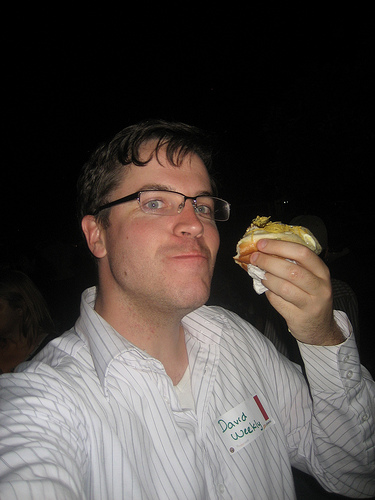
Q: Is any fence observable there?
A: No, there are no fences.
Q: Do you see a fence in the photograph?
A: No, there are no fences.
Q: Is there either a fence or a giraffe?
A: No, there are no fences or giraffes.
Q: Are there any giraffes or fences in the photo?
A: No, there are no fences or giraffes.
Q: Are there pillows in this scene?
A: No, there are no pillows.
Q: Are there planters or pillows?
A: No, there are no pillows or planters.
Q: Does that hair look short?
A: Yes, the hair is short.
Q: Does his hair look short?
A: Yes, the hair is short.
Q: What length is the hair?
A: The hair is short.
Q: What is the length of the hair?
A: The hair is short.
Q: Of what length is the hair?
A: The hair is short.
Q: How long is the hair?
A: The hair is short.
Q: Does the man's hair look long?
A: No, the hair is short.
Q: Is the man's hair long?
A: No, the hair is short.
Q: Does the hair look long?
A: No, the hair is short.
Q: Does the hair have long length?
A: No, the hair is short.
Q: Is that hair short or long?
A: The hair is short.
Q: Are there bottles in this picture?
A: No, there are no bottles.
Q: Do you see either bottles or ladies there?
A: No, there are no bottles or ladies.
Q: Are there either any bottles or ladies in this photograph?
A: No, there are no bottles or ladies.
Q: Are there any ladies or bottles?
A: No, there are no bottles or ladies.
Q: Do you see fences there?
A: No, there are no fences.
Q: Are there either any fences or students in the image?
A: No, there are no fences or students.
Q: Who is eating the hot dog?
A: The man is eating the hot dog.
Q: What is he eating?
A: The man is eating a hot dog.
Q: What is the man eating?
A: The man is eating a hot dog.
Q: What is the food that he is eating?
A: The food is a hot dog.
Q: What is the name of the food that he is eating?
A: The food is a hot dog.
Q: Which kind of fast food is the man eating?
A: The man is eating a hot dog.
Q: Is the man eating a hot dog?
A: Yes, the man is eating a hot dog.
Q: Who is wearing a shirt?
A: The man is wearing a shirt.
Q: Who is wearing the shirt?
A: The man is wearing a shirt.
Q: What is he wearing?
A: The man is wearing a shirt.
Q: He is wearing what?
A: The man is wearing a shirt.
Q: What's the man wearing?
A: The man is wearing a shirt.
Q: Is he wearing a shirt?
A: Yes, the man is wearing a shirt.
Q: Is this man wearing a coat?
A: No, the man is wearing a shirt.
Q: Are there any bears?
A: No, there are no bears.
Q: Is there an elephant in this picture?
A: No, there are no elephants.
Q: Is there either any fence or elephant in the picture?
A: No, there are no elephants or fences.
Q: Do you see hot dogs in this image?
A: Yes, there is a hot dog.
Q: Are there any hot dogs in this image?
A: Yes, there is a hot dog.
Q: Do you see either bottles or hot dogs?
A: Yes, there is a hot dog.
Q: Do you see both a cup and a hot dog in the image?
A: No, there is a hot dog but no cups.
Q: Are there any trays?
A: No, there are no trays.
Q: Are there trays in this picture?
A: No, there are no trays.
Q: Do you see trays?
A: No, there are no trays.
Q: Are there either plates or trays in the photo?
A: No, there are no trays or plates.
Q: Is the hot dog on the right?
A: Yes, the hot dog is on the right of the image.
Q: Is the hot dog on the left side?
A: No, the hot dog is on the right of the image.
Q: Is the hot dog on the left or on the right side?
A: The hot dog is on the right of the image.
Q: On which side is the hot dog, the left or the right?
A: The hot dog is on the right of the image.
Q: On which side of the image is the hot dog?
A: The hot dog is on the right of the image.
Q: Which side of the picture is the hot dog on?
A: The hot dog is on the right of the image.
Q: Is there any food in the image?
A: Yes, there is food.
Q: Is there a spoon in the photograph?
A: No, there are no spoons.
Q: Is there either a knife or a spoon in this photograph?
A: No, there are no spoons or knives.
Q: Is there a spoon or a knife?
A: No, there are no spoons or knives.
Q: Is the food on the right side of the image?
A: Yes, the food is on the right of the image.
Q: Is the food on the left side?
A: No, the food is on the right of the image.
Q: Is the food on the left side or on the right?
A: The food is on the right of the image.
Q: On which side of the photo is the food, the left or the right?
A: The food is on the right of the image.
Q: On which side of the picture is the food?
A: The food is on the right of the image.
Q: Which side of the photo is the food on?
A: The food is on the right of the image.